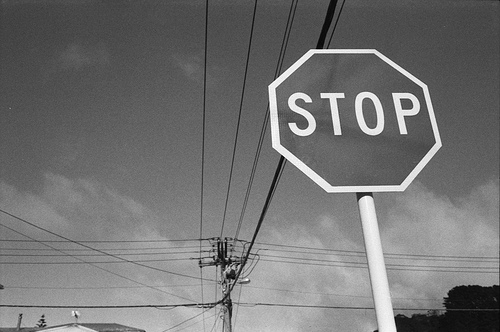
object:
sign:
[266, 48, 443, 193]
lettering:
[390, 91, 420, 136]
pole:
[350, 192, 399, 331]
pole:
[214, 262, 236, 331]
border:
[266, 48, 443, 196]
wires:
[217, 0, 260, 239]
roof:
[67, 321, 146, 330]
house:
[0, 309, 147, 331]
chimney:
[18, 312, 26, 330]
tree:
[35, 308, 54, 329]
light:
[233, 275, 253, 285]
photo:
[0, 1, 499, 332]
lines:
[198, 0, 209, 331]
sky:
[0, 0, 499, 331]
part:
[374, 243, 378, 247]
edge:
[322, 28, 328, 38]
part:
[103, 209, 108, 211]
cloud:
[0, 171, 499, 331]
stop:
[286, 90, 421, 139]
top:
[38, 313, 47, 319]